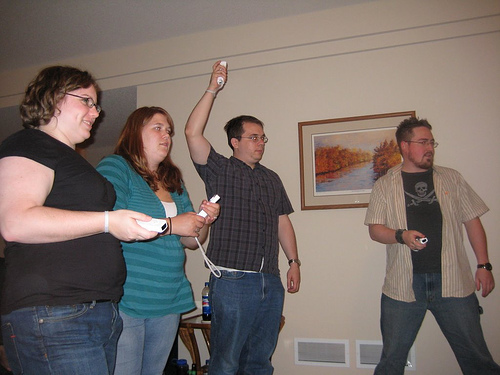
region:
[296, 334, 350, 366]
a white wall vent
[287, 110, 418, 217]
part of a brown picture frame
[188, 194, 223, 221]
a white wii game controller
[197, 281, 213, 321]
a large pepsi bottle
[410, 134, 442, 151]
a man's eyeglasses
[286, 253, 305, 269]
a man's wristwatch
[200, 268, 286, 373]
part of a man's jean pants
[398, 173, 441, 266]
a man's black and white shirt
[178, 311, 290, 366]
part of a small table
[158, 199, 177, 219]
part of a woman's white shirt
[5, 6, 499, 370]
people playing in a room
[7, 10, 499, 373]
people holding game comands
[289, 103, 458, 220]
a picture behind a man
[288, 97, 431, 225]
painting of a landscape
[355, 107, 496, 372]
man holds a game command on right hand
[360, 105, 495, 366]
man wears glasses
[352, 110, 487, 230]
man has short hair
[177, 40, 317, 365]
man holds a game command up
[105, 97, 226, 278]
woman holds a game game command with both hands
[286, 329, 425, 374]
two bents on wall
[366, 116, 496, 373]
A man in a black shirt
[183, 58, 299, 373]
A man in a black shirt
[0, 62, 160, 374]
A woman in a black shirt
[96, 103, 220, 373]
A woman in a blue shirt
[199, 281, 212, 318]
A bottle of pepsi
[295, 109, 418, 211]
A picture on the wall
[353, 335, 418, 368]
A white vent on the wall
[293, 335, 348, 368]
A white vent on the wall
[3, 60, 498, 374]
A group of people playing video games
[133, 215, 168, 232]
A white video game controller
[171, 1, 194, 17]
part of a ceiling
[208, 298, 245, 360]
part of a trouser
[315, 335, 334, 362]
part of a socket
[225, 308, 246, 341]
part of a trouser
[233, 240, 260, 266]
part of a shirt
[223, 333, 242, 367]
part of a jeans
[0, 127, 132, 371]
woman wearing black shirt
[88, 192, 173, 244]
woman holding game controller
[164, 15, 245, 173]
man's arm in the air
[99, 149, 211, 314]
woman's shirt is blue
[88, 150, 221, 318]
woman's shirt is striped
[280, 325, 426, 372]
white vents on the wall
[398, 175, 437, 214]
skull on man's shirt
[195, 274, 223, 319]
blue bottle behind man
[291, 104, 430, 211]
painting on the wall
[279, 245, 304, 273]
man wearing a watch